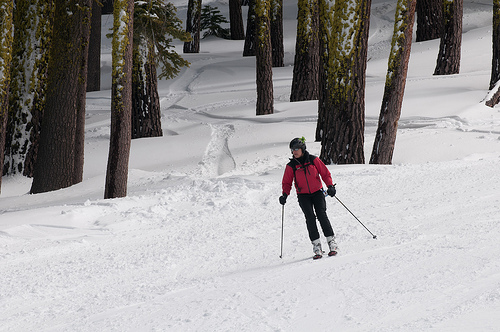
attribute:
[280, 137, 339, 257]
person — skier, ready to ski, skiing, skiing downhill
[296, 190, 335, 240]
pants — black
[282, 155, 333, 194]
jacket — pink, red, winter coat, bright pink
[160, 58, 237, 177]
snow trail — multi directional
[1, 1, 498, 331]
ground — sloppy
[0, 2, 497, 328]
snow — white, abundant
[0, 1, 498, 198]
trees — close together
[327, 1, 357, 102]
moss — green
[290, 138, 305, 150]
helmet — black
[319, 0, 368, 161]
tree — large, snowy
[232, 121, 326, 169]
snow — unbothered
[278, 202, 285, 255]
ski pole — black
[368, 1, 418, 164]
tree — brown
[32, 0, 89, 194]
tree — brown, large, snowy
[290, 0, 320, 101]
tree — brown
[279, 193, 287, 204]
ski glove — black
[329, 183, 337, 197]
ski glove — black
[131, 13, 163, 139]
tree — large, snowy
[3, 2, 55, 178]
tree — large, snowy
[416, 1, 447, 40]
tree — large, snowy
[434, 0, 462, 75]
tree — large, snowy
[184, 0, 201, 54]
tree — large, snowy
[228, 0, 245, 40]
tree — small, snowy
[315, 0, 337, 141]
tree — small, snowy